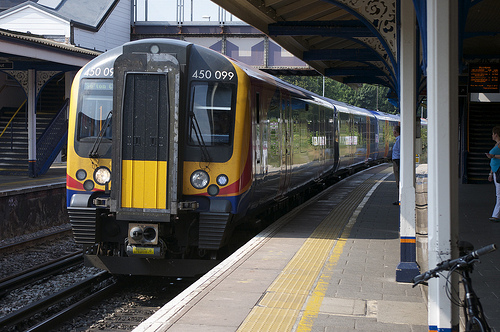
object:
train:
[65, 36, 428, 281]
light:
[93, 166, 112, 185]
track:
[22, 281, 118, 331]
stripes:
[290, 170, 393, 331]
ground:
[133, 159, 500, 331]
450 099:
[191, 67, 236, 82]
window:
[184, 80, 237, 149]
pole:
[433, 0, 453, 330]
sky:
[133, 0, 243, 23]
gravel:
[0, 217, 195, 332]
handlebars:
[467, 242, 495, 259]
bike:
[410, 236, 499, 330]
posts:
[394, 0, 423, 285]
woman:
[484, 125, 500, 222]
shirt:
[488, 144, 498, 174]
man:
[390, 124, 403, 206]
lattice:
[327, 0, 401, 86]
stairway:
[0, 70, 70, 177]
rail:
[0, 99, 26, 153]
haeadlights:
[188, 169, 211, 190]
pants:
[492, 172, 500, 217]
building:
[1, 0, 136, 52]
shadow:
[248, 159, 398, 240]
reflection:
[79, 52, 121, 78]